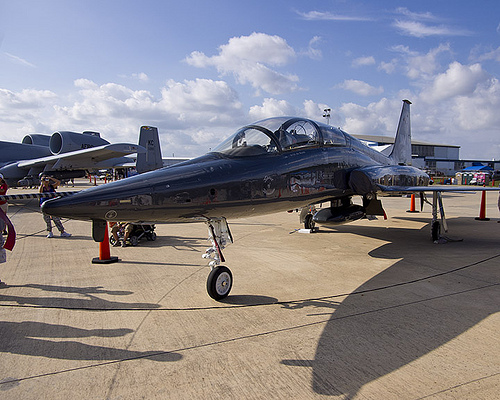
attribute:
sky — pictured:
[262, 51, 373, 111]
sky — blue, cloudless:
[52, 23, 414, 124]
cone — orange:
[89, 217, 122, 266]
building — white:
[356, 135, 461, 178]